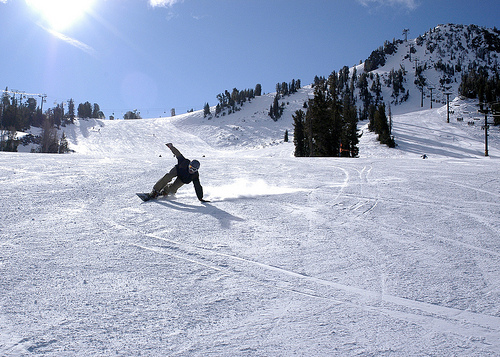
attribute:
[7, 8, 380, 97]
sky — clear, blue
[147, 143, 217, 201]
snowboarder — sliding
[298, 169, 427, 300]
lines — white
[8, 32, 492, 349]
snow — fresh, smooth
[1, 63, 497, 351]
snow — white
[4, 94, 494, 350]
snow — white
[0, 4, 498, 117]
sky — clear , blue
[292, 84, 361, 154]
trees — Green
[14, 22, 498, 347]
hill — white, snowy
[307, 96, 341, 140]
leaves — green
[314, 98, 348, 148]
leaves — green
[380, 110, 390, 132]
leaves — green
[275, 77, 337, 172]
leaves — green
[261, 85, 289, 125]
leaves — green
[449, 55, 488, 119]
leaves — green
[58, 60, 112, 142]
leaves — green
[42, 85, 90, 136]
leaves — green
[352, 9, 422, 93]
leaves — green